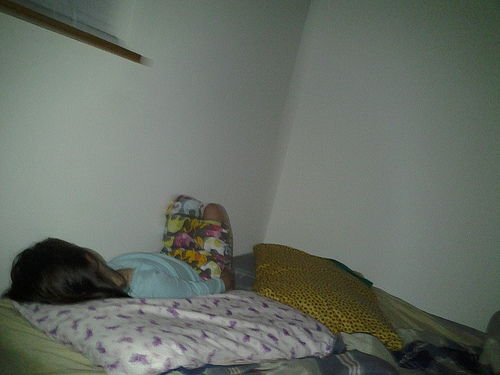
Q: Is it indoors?
A: Yes, it is indoors.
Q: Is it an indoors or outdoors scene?
A: It is indoors.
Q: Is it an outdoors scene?
A: No, it is indoors.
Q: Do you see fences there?
A: No, there are no fences.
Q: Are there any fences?
A: No, there are no fences.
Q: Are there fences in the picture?
A: No, there are no fences.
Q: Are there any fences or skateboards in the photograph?
A: No, there are no fences or skateboards.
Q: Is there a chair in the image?
A: No, there are no chairs.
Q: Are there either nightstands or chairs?
A: No, there are no chairs or nightstands.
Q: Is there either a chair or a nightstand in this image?
A: No, there are no chairs or nightstands.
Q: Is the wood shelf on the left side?
A: Yes, the shelf is on the left of the image.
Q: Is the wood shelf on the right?
A: No, the shelf is on the left of the image.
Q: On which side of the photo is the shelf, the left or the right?
A: The shelf is on the left of the image.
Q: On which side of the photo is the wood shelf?
A: The shelf is on the left of the image.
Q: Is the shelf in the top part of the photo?
A: Yes, the shelf is in the top of the image.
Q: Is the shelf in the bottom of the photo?
A: No, the shelf is in the top of the image.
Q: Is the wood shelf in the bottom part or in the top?
A: The shelf is in the top of the image.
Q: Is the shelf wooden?
A: Yes, the shelf is wooden.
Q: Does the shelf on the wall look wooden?
A: Yes, the shelf is wooden.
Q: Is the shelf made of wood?
A: Yes, the shelf is made of wood.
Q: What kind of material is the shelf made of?
A: The shelf is made of wood.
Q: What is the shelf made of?
A: The shelf is made of wood.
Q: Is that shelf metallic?
A: No, the shelf is wooden.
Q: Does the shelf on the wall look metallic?
A: No, the shelf is wooden.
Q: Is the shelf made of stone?
A: No, the shelf is made of wood.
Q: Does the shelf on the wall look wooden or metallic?
A: The shelf is wooden.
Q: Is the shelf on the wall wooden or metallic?
A: The shelf is wooden.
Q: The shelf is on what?
A: The shelf is on the wall.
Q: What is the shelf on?
A: The shelf is on the wall.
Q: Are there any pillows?
A: Yes, there is a pillow.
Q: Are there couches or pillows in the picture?
A: Yes, there is a pillow.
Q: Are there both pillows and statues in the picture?
A: No, there is a pillow but no statues.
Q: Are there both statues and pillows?
A: No, there is a pillow but no statues.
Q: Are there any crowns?
A: No, there are no crowns.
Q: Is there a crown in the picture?
A: No, there are no crowns.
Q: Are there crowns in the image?
A: No, there are no crowns.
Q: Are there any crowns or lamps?
A: No, there are no crowns or lamps.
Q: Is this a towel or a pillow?
A: This is a pillow.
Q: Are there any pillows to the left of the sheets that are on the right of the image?
A: Yes, there is a pillow to the left of the sheets.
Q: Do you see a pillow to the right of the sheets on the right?
A: No, the pillow is to the left of the sheets.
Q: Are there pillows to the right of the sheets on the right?
A: No, the pillow is to the left of the sheets.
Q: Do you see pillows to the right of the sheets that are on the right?
A: No, the pillow is to the left of the sheets.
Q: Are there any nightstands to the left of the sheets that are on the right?
A: No, there is a pillow to the left of the sheets.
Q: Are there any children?
A: Yes, there is a child.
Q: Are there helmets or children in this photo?
A: Yes, there is a child.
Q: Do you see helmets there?
A: No, there are no helmets.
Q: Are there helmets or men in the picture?
A: No, there are no helmets or men.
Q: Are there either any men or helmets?
A: No, there are no helmets or men.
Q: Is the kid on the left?
A: Yes, the kid is on the left of the image.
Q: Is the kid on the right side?
A: No, the kid is on the left of the image.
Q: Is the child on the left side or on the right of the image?
A: The child is on the left of the image.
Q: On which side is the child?
A: The child is on the left of the image.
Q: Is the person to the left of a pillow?
A: Yes, the child is to the left of a pillow.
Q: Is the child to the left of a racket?
A: No, the child is to the left of a pillow.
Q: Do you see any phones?
A: No, there are no phones.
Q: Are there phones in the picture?
A: No, there are no phones.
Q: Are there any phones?
A: No, there are no phones.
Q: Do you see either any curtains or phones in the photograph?
A: No, there are no phones or curtains.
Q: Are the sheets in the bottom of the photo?
A: Yes, the sheets are in the bottom of the image.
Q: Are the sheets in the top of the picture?
A: No, the sheets are in the bottom of the image.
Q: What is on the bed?
A: The sheets are on the bed.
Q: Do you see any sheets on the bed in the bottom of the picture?
A: Yes, there are sheets on the bed.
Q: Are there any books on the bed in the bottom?
A: No, there are sheets on the bed.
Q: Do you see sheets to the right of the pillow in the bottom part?
A: Yes, there are sheets to the right of the pillow.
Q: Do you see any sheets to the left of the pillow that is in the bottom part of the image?
A: No, the sheets are to the right of the pillow.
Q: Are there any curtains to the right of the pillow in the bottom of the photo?
A: No, there are sheets to the right of the pillow.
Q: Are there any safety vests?
A: No, there are no safety vests.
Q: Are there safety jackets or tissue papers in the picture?
A: No, there are no safety jackets or tissue papers.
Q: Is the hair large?
A: Yes, the hair is large.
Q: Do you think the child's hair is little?
A: No, the hair is large.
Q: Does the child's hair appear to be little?
A: No, the hair is large.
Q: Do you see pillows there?
A: Yes, there is a pillow.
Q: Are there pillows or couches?
A: Yes, there is a pillow.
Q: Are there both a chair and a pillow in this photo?
A: No, there is a pillow but no chairs.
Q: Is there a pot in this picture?
A: No, there are no pots.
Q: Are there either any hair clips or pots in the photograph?
A: No, there are no pots or hair clips.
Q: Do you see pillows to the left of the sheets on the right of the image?
A: Yes, there is a pillow to the left of the sheets.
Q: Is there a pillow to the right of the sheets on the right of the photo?
A: No, the pillow is to the left of the sheets.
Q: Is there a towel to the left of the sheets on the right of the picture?
A: No, there is a pillow to the left of the sheets.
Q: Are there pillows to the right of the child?
A: Yes, there is a pillow to the right of the child.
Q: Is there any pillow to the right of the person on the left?
A: Yes, there is a pillow to the right of the child.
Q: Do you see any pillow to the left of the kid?
A: No, the pillow is to the right of the kid.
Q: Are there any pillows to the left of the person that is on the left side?
A: No, the pillow is to the right of the kid.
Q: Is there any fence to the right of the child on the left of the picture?
A: No, there is a pillow to the right of the child.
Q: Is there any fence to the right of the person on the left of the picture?
A: No, there is a pillow to the right of the child.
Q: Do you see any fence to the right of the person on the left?
A: No, there is a pillow to the right of the child.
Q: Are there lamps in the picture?
A: No, there are no lamps.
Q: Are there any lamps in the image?
A: No, there are no lamps.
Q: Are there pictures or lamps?
A: No, there are no lamps or pictures.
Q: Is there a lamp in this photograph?
A: No, there are no lamps.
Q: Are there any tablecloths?
A: No, there are no tablecloths.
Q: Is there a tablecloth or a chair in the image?
A: No, there are no tablecloths or chairs.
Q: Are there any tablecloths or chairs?
A: No, there are no tablecloths or chairs.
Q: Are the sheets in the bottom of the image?
A: Yes, the sheets are in the bottom of the image.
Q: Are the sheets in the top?
A: No, the sheets are in the bottom of the image.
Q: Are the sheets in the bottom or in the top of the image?
A: The sheets are in the bottom of the image.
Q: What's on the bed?
A: The sheets are on the bed.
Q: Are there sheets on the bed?
A: Yes, there are sheets on the bed.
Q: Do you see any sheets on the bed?
A: Yes, there are sheets on the bed.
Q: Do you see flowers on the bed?
A: No, there are sheets on the bed.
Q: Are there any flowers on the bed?
A: No, there are sheets on the bed.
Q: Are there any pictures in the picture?
A: No, there are no pictures.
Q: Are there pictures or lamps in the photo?
A: No, there are no pictures or lamps.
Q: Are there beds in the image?
A: Yes, there is a bed.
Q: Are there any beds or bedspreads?
A: Yes, there is a bed.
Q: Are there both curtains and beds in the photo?
A: No, there is a bed but no curtains.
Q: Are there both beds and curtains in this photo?
A: No, there is a bed but no curtains.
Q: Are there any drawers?
A: No, there are no drawers.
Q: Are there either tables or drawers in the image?
A: No, there are no drawers or tables.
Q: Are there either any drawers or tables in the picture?
A: No, there are no drawers or tables.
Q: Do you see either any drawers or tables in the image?
A: No, there are no drawers or tables.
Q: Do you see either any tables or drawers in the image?
A: No, there are no drawers or tables.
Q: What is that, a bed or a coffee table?
A: That is a bed.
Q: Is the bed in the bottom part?
A: Yes, the bed is in the bottom of the image.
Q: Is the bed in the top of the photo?
A: No, the bed is in the bottom of the image.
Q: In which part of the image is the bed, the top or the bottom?
A: The bed is in the bottom of the image.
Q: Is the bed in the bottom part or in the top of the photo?
A: The bed is in the bottom of the image.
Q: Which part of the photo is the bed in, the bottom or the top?
A: The bed is in the bottom of the image.